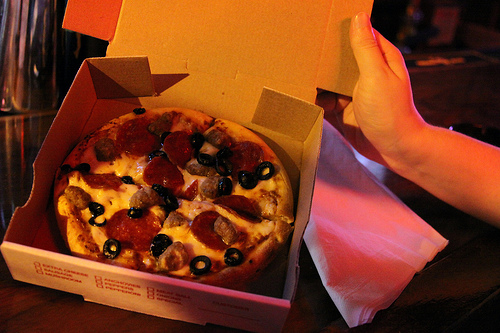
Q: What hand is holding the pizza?
A: There isn't a pizza.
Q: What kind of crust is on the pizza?
A: There isn't one.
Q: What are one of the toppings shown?
A: Cheese.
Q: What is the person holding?
A: Box.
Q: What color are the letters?
A: Red.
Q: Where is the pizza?
A: In box.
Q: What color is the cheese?
A: White.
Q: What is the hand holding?
A: Cardboard.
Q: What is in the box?
A: Pizza.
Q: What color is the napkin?
A: White.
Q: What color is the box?
A: Brown.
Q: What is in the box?
A: Pizza.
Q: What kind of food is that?
A: Pizza.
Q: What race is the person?
A: White.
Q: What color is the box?
A: Brown.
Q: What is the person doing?
A: Holding a box.